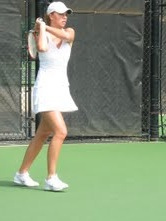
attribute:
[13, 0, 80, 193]
girl — playing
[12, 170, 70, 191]
shoes — white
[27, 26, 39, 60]
racquet — tennis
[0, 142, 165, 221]
court — green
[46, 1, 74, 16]
cap — white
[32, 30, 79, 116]
dress — white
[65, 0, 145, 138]
backdrop — grey, blind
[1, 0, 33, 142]
gate — chain link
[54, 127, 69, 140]
knee — bent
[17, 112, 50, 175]
leg — straight